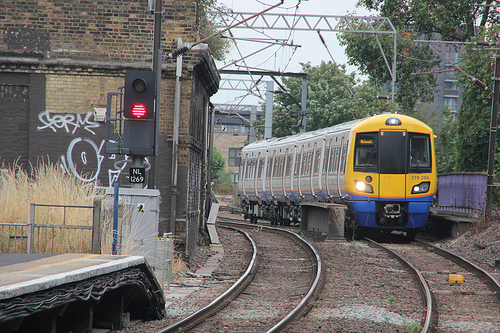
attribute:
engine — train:
[274, 83, 444, 226]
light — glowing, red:
[126, 101, 148, 124]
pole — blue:
[108, 181, 121, 254]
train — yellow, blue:
[230, 110, 456, 235]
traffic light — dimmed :
[116, 49, 163, 166]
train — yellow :
[196, 80, 443, 247]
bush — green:
[316, 75, 357, 118]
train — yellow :
[240, 112, 440, 243]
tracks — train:
[165, 187, 499, 329]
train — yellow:
[243, 112, 427, 232]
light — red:
[130, 103, 147, 120]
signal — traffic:
[106, 62, 171, 164]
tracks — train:
[281, 249, 403, 271]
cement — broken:
[165, 243, 231, 310]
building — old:
[2, 0, 221, 277]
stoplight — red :
[119, 65, 156, 151]